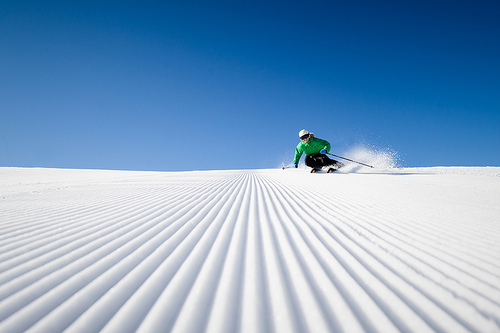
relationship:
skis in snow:
[307, 160, 345, 176] [0, 171, 471, 320]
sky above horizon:
[1, 0, 498, 172] [3, 145, 483, 186]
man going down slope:
[294, 129, 346, 174] [175, 171, 419, 317]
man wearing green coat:
[294, 129, 346, 174] [293, 135, 331, 165]